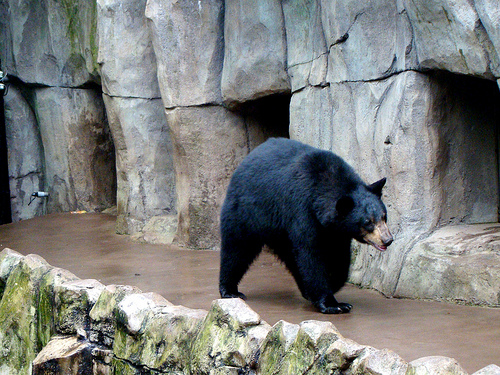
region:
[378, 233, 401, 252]
Bear has black nose.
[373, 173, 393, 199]
Bear has black ear.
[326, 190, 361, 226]
Bear has black ear.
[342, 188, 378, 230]
Bear has black head.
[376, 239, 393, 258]
Bear has pink tongue.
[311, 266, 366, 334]
Bear has black paw.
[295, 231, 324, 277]
Bear has black leg.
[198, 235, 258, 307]
Bear has black back leg.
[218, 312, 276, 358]
Large gray rock wall near bear.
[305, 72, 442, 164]
Gray rock wall behind bear.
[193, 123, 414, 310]
a black bear walking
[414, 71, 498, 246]
opening of a rock cave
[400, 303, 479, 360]
pathway for a bear to walk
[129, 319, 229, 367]
moss growing on a bear's enclosure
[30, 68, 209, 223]
rock wall of an enclosure for an animal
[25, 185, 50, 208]
a camera attached to a wall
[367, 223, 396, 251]
snout of a black bear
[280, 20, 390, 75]
crack in a rock wall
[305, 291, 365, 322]
a bear's paws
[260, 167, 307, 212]
black fur of a bear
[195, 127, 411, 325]
a black bear in a zoo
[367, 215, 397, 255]
the snout of bear is brown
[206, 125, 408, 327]
the bear is color black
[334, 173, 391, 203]
two pointy ears of bear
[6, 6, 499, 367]
pen of bear has rocks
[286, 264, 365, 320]
front legs of bear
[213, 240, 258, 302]
back leg of bear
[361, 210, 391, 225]
eyes of bear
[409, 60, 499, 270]
entrance on wall of rock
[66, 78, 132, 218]
entrance on wall of rock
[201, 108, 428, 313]
Black bear on the rocks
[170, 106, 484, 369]
Black furry bear.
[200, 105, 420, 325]
Black bear in a zoo.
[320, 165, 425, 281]
Light face on the bear.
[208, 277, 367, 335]
Paws on the bear.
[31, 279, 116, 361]
Moss on the rocks.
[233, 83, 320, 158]
opening in the stone.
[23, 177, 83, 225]
Camera on the rock.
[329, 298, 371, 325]
Claws on the bear.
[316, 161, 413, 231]
Ears on the bear.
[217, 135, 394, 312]
a black bear in the zoo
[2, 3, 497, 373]
a habitat for the bear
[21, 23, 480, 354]
the habitat for the bears in a zoo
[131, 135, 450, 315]
a black bear walking on a concrete walkway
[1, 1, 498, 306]
wall stones in the bear's habitat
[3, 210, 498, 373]
the walkway inside the bear's habitat at the zoo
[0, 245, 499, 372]
a green and gray wall to a lower level at the zoo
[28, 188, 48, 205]
a device on the lower part of the stone wall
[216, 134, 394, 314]
a bear walking on the walkway inside a zoo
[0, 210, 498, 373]
a brown walkway inside the bear's habitat